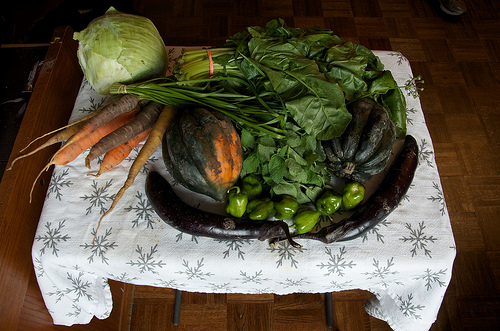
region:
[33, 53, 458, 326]
A towel on the table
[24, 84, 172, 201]
CArrots by the lettuce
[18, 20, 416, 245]
Vegetables on the cloth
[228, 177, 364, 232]
Peppers near the spinach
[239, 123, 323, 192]
Spinach on the white cloth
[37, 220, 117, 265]
A snowflake design on the cloth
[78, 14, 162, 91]
Lettuce by the carrots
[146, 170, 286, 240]
A black vegetable by the peppers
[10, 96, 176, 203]
The carrots are dark and orange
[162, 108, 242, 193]
A gourd by the peppers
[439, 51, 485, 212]
The floor is made of wood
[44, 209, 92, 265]
The tablecloth on the table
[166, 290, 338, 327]
The legs on the table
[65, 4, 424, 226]
Raw fruit sitting on the table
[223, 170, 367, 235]
The peppers are the color green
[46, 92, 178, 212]
The carrots are the color orange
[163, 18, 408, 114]
The collard greens on the table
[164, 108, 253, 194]
The squash on the table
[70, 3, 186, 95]
A cabbage on the table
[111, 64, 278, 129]
The green onions on the table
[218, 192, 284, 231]
the peppers are green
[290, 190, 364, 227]
the peppers are green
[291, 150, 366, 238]
the peppers are green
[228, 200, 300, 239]
the peppers are green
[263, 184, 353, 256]
the peppers are green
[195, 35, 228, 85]
the ribbon is pink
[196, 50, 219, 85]
the ribbon is pink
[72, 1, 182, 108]
the cabbage is green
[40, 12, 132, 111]
the cabbage is green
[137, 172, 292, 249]
a long, purple eggplant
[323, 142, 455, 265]
a long, purple eggplant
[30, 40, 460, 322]
white tablecloth with snowflake pattern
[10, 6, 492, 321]
table legs on floor of wooden squares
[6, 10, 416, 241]
vegetables displayed on table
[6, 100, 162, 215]
long orange and gray carrots with thin roots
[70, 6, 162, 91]
green cabbage on table corner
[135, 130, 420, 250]
eggplants curving around vegetables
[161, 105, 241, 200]
ridged orange and green squash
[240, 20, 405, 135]
long ruffled green leaves with center stem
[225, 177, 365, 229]
round and shiny green peppers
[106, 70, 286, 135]
slender scallions tied with rubber band